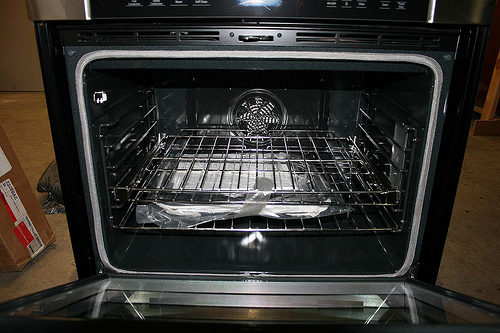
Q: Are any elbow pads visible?
A: No, there are no elbow pads.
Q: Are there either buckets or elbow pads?
A: No, there are no elbow pads or buckets.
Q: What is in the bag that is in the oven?
A: The papers are in the bag.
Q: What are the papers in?
A: The papers are in the bag.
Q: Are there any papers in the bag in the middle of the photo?
A: Yes, there are papers in the bag.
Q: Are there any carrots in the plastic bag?
A: No, there are papers in the bag.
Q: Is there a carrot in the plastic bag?
A: No, there are papers in the bag.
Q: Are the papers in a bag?
A: Yes, the papers are in a bag.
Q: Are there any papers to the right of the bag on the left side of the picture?
A: Yes, there are papers to the right of the bag.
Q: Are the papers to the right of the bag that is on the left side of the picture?
A: Yes, the papers are to the right of the bag.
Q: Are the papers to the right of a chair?
A: No, the papers are to the right of the bag.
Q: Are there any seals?
A: Yes, there is a seal.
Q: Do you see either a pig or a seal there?
A: Yes, there is a seal.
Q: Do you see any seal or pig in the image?
A: Yes, there is a seal.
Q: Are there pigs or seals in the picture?
A: Yes, there is a seal.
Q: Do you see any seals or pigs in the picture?
A: Yes, there is a seal.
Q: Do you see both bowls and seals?
A: No, there is a seal but no bowls.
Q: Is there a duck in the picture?
A: No, there are no ducks.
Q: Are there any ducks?
A: No, there are no ducks.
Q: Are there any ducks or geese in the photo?
A: No, there are no ducks or geese.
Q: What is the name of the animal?
A: The animal is a seal.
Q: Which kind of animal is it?
A: The animal is a seal.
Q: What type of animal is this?
A: This is a seal.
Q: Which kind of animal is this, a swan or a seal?
A: This is a seal.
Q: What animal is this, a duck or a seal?
A: This is a seal.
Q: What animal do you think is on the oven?
A: The seal is on the oven.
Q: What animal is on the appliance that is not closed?
A: The seal is on the oven.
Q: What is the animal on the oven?
A: The animal is a seal.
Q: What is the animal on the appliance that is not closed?
A: The animal is a seal.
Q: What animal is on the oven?
A: The animal is a seal.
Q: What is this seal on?
A: The seal is on the oven.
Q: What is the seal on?
A: The seal is on the oven.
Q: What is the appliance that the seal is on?
A: The appliance is an oven.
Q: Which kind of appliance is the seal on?
A: The seal is on the oven.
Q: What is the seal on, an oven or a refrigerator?
A: The seal is on an oven.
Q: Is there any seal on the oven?
A: Yes, there is a seal on the oven.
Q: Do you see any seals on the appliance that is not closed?
A: Yes, there is a seal on the oven.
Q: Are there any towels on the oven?
A: No, there is a seal on the oven.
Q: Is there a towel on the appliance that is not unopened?
A: No, there is a seal on the oven.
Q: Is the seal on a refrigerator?
A: No, the seal is on the oven.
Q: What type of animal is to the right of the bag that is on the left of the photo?
A: The animal is a seal.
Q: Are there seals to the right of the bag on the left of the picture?
A: Yes, there is a seal to the right of the bag.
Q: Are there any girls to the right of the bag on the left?
A: No, there is a seal to the right of the bag.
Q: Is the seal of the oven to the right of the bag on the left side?
A: Yes, the seal is to the right of the bag.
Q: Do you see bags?
A: Yes, there is a bag.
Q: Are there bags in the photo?
A: Yes, there is a bag.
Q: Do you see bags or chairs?
A: Yes, there is a bag.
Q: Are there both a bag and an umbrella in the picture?
A: No, there is a bag but no umbrellas.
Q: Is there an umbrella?
A: No, there are no umbrellas.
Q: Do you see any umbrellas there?
A: No, there are no umbrellas.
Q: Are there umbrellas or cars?
A: No, there are no umbrellas or cars.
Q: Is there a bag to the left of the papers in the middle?
A: Yes, there is a bag to the left of the papers.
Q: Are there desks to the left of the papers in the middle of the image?
A: No, there is a bag to the left of the papers.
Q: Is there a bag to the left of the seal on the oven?
A: Yes, there is a bag to the left of the seal.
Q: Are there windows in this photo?
A: Yes, there is a window.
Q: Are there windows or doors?
A: Yes, there is a window.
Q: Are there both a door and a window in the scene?
A: Yes, there are both a window and a door.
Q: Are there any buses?
A: No, there are no buses.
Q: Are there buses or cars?
A: No, there are no buses or cars.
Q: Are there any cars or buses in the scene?
A: No, there are no buses or cars.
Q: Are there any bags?
A: Yes, there is a bag.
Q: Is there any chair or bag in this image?
A: Yes, there is a bag.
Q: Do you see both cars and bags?
A: No, there is a bag but no cars.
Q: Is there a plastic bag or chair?
A: Yes, there is a plastic bag.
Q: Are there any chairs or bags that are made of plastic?
A: Yes, the bag is made of plastic.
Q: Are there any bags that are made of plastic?
A: Yes, there is a bag that is made of plastic.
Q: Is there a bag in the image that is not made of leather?
A: Yes, there is a bag that is made of plastic.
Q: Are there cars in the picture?
A: No, there are no cars.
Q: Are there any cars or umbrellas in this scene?
A: No, there are no cars or umbrellas.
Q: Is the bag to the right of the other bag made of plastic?
A: Yes, the bag is made of plastic.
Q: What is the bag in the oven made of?
A: The bag is made of plastic.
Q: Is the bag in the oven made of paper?
A: No, the bag is made of plastic.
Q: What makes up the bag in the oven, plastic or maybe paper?
A: The bag is made of plastic.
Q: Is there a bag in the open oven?
A: Yes, there is a bag in the oven.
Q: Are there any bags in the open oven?
A: Yes, there is a bag in the oven.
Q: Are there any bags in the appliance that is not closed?
A: Yes, there is a bag in the oven.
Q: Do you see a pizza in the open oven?
A: No, there is a bag in the oven.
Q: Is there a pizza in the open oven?
A: No, there is a bag in the oven.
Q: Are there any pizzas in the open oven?
A: No, there is a bag in the oven.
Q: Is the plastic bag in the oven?
A: Yes, the bag is in the oven.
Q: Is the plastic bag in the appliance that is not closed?
A: Yes, the bag is in the oven.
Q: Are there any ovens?
A: Yes, there is an oven.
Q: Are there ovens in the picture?
A: Yes, there is an oven.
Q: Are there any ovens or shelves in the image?
A: Yes, there is an oven.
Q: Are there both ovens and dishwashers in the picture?
A: No, there is an oven but no dishwashers.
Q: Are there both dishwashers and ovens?
A: No, there is an oven but no dishwashers.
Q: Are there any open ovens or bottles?
A: Yes, there is an open oven.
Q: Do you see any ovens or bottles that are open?
A: Yes, the oven is open.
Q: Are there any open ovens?
A: Yes, there is an open oven.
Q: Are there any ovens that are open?
A: Yes, there is an oven that is open.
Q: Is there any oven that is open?
A: Yes, there is an oven that is open.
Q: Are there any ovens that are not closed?
A: Yes, there is a open oven.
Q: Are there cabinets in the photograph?
A: No, there are no cabinets.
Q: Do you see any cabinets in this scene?
A: No, there are no cabinets.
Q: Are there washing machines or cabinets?
A: No, there are no cabinets or washing machines.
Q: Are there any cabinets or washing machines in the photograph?
A: No, there are no cabinets or washing machines.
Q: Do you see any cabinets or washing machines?
A: No, there are no cabinets or washing machines.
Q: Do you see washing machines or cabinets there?
A: No, there are no cabinets or washing machines.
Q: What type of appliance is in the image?
A: The appliance is an oven.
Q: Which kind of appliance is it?
A: The appliance is an oven.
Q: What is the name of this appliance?
A: This is an oven.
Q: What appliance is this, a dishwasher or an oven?
A: This is an oven.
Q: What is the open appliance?
A: The appliance is an oven.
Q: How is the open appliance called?
A: The appliance is an oven.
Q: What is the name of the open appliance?
A: The appliance is an oven.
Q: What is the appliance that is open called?
A: The appliance is an oven.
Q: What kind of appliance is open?
A: The appliance is an oven.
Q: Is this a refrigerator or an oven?
A: This is an oven.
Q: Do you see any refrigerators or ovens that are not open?
A: No, there is an oven but it is open.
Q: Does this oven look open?
A: Yes, the oven is open.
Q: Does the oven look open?
A: Yes, the oven is open.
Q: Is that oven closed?
A: No, the oven is open.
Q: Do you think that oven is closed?
A: No, the oven is open.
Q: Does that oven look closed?
A: No, the oven is open.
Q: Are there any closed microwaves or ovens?
A: No, there is an oven but it is open.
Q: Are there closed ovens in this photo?
A: No, there is an oven but it is open.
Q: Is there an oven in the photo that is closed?
A: No, there is an oven but it is open.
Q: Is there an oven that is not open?
A: No, there is an oven but it is open.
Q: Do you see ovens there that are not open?
A: No, there is an oven but it is open.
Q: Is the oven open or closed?
A: The oven is open.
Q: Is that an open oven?
A: Yes, that is an open oven.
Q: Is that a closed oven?
A: No, that is an open oven.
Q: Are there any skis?
A: No, there are no skis.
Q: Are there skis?
A: No, there are no skis.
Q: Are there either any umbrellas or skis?
A: No, there are no skis or umbrellas.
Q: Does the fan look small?
A: Yes, the fan is small.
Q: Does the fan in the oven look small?
A: Yes, the fan is small.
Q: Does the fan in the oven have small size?
A: Yes, the fan is small.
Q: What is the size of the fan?
A: The fan is small.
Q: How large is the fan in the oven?
A: The fan is small.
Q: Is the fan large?
A: No, the fan is small.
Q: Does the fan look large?
A: No, the fan is small.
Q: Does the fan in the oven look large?
A: No, the fan is small.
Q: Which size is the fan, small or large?
A: The fan is small.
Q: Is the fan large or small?
A: The fan is small.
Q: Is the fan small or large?
A: The fan is small.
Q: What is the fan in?
A: The fan is in the oven.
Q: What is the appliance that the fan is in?
A: The appliance is an oven.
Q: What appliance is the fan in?
A: The fan is in the oven.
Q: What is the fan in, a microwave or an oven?
A: The fan is in an oven.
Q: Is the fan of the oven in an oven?
A: Yes, the fan is in an oven.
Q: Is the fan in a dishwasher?
A: No, the fan is in an oven.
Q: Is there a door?
A: Yes, there is a door.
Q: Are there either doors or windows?
A: Yes, there is a door.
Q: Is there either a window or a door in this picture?
A: Yes, there is a door.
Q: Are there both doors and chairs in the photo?
A: No, there is a door but no chairs.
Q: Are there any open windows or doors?
A: Yes, there is an open door.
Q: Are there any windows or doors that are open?
A: Yes, the door is open.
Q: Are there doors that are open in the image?
A: Yes, there is an open door.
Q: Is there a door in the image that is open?
A: Yes, there is a door that is open.